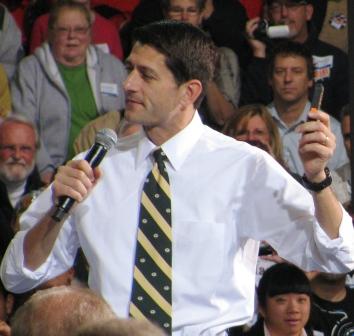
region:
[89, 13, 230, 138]
head of the man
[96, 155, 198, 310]
colorful tie on man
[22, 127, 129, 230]
microphone in man's hand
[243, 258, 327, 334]
head of a woman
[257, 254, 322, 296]
black hair on woman's head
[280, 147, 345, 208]
object around wrist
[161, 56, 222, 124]
ear on the man's head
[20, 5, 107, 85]
head of an older woman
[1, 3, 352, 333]
man giving a speech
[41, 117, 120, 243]
a hand holding a microphone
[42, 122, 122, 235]
the microphone is black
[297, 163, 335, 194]
the watch is black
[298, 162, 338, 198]
a watch on a wrist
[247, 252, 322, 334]
man has black hair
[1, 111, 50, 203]
man with white hair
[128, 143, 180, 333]
the tie is yellow and balck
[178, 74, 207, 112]
the ear of a person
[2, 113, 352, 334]
a long sleeve shirt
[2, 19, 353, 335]
the man with the microphone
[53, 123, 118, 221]
the microphone in the mans hand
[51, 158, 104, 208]
the hand holding the microphone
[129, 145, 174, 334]
the black and yellow stripped tie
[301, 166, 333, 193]
the black watch on the man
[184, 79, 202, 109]
the ear on the man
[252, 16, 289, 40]
the camera in the hand of the man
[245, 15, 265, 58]
the hand holding the camera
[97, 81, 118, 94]
the tag on the grey sweater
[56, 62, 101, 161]
the green tee shirt on the woman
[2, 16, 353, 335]
man talking into microphone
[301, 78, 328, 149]
marker in man's hand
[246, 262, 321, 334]
girl watching the speaker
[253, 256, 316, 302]
girl has black hair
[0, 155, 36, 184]
man has a beard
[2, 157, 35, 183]
man's beard is white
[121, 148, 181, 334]
speaker wearing a tie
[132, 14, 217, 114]
speaker has short hair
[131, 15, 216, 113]
speakers hair is brown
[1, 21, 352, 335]
Representative Paul Ryan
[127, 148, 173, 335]
a multi colored tie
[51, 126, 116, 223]
a hand held microphone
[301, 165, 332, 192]
a black wrist watch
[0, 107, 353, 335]
a long sleeve white shirt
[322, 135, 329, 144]
a man's wedding band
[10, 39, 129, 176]
a grey hooded jacket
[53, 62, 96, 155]
a woman's green shirt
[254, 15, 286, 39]
an open silver camcorder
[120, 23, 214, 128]
a caucasian man's face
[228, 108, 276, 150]
A person is sitting down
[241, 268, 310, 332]
A person is sitting down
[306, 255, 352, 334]
A person is sitting down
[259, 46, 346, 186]
A person is sitting down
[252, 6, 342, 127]
A person is sitting down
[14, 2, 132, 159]
A person is sitting down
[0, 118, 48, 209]
A person is sitting down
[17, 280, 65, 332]
A person is sitting down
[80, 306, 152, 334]
A person is sitting down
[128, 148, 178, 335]
yellow and black colored tie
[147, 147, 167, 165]
knot of a tie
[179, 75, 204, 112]
man's left ear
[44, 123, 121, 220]
mic in a man's right hand